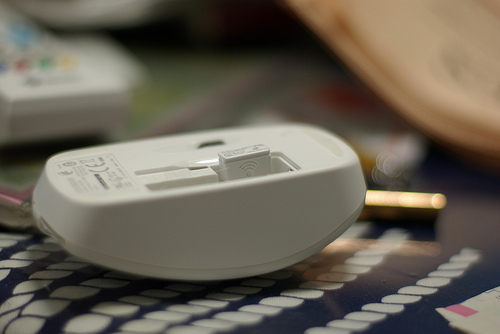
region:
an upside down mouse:
[29, 120, 370, 286]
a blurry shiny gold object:
[361, 185, 448, 220]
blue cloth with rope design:
[0, 226, 482, 332]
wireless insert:
[216, 141, 273, 182]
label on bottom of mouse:
[57, 148, 136, 200]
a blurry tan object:
[299, 0, 497, 179]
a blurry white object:
[1, 0, 143, 140]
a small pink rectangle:
[445, 301, 480, 318]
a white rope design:
[306, 246, 478, 332]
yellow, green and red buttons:
[14, 55, 80, 72]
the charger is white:
[24, 29, 430, 329]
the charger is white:
[76, 54, 319, 271]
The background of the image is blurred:
[1, 1, 499, 158]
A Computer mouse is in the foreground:
[25, 105, 380, 295]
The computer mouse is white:
[10, 100, 400, 305]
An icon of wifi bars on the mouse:
[220, 145, 270, 180]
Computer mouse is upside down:
[18, 110, 371, 301]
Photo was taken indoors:
[3, 1, 498, 331]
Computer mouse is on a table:
[8, 233, 454, 331]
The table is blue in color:
[2, 236, 447, 331]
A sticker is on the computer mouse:
[46, 142, 131, 202]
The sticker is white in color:
[51, 145, 136, 198]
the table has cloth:
[56, 36, 354, 332]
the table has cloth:
[86, 121, 321, 281]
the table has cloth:
[189, 188, 301, 328]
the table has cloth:
[236, 111, 389, 328]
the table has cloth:
[334, 233, 398, 323]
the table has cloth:
[289, 227, 368, 332]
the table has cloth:
[347, 178, 425, 327]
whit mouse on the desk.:
[30, 107, 372, 284]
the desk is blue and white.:
[3, 192, 495, 328]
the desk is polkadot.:
[5, 227, 497, 332]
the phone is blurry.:
[0, 0, 147, 137]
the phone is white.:
[2, 2, 161, 141]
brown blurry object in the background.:
[292, 0, 497, 164]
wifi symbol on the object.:
[230, 154, 261, 180]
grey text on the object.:
[54, 150, 133, 196]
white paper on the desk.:
[429, 274, 499, 329]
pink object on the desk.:
[1, 157, 47, 218]